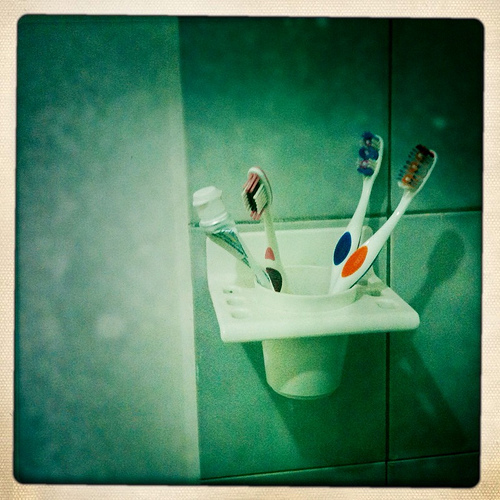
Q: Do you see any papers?
A: No, there are no papers.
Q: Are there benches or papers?
A: No, there are no papers or benches.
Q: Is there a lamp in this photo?
A: No, there are no lamps.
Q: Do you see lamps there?
A: No, there are no lamps.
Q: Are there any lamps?
A: No, there are no lamps.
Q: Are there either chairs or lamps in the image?
A: No, there are no lamps or chairs.